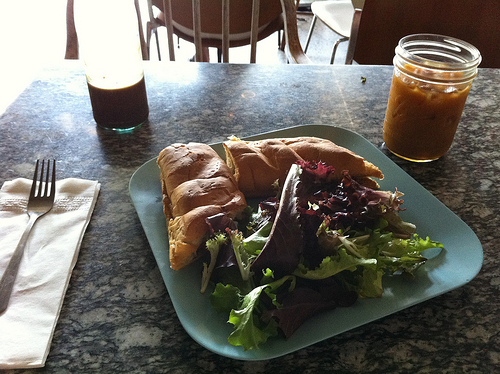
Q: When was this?
A: Daytime.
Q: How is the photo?
A: Clear.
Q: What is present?
A: Food.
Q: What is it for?
A: Eating.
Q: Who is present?
A: Nobody.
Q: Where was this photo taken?
A: In a restaurant.